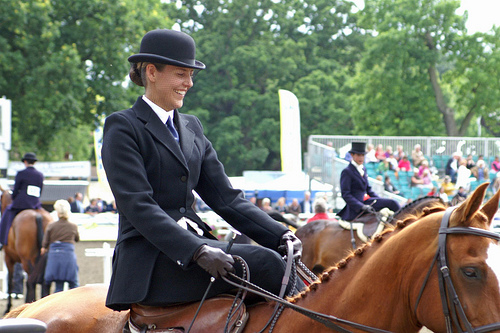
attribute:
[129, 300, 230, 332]
saddle — brown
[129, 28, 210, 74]
hat — black, round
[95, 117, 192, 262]
sleeve — black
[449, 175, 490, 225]
ear — brown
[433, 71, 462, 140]
branch — brown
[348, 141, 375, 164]
hat — black, tall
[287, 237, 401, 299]
mane — brown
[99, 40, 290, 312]
woman — happy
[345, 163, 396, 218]
suit — black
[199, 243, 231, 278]
gloves — black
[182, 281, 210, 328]
crop — black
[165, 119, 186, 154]
tie — black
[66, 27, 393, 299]
lady — grinning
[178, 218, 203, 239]
shirt — white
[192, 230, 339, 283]
hands — covered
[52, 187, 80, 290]
person — standing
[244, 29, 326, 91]
leaves — green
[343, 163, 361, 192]
jacket — black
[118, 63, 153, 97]
hair — up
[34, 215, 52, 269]
tail — black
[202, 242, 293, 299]
pants — black